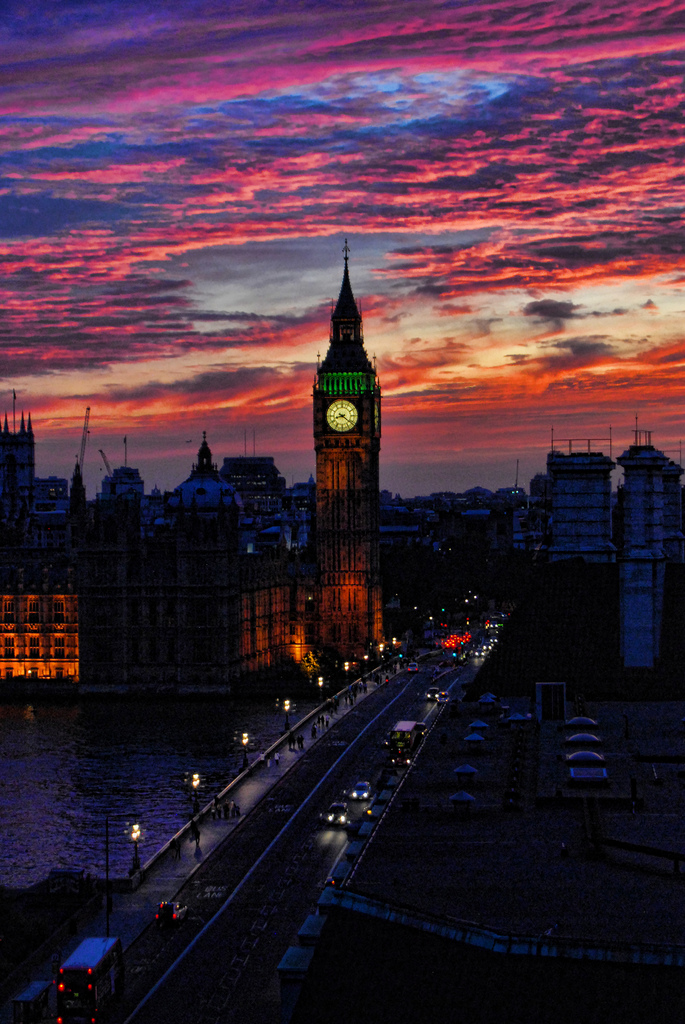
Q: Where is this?
A: This is at the city.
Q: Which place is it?
A: It is a city.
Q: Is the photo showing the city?
A: Yes, it is showing the city.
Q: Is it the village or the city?
A: It is the city.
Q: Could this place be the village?
A: No, it is the city.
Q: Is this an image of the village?
A: No, the picture is showing the city.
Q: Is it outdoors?
A: Yes, it is outdoors.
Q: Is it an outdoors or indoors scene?
A: It is outdoors.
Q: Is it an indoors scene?
A: No, it is outdoors.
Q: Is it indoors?
A: No, it is outdoors.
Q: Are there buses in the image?
A: Yes, there is a bus.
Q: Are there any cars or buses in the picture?
A: Yes, there is a bus.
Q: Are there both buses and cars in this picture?
A: Yes, there are both a bus and a car.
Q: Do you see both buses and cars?
A: Yes, there are both a bus and a car.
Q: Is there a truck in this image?
A: No, there are no trucks.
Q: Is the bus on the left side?
A: Yes, the bus is on the left of the image.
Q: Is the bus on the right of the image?
A: No, the bus is on the left of the image.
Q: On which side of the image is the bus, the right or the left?
A: The bus is on the left of the image.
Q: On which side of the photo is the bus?
A: The bus is on the left of the image.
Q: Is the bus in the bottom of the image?
A: Yes, the bus is in the bottom of the image.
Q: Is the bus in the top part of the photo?
A: No, the bus is in the bottom of the image.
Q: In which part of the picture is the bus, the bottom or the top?
A: The bus is in the bottom of the image.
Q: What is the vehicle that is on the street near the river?
A: The vehicle is a bus.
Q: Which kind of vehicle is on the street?
A: The vehicle is a bus.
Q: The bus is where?
A: The bus is on the street.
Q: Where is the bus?
A: The bus is on the street.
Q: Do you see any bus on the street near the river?
A: Yes, there is a bus on the street.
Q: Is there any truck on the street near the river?
A: No, there is a bus on the street.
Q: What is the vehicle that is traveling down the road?
A: The vehicle is a bus.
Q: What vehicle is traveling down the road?
A: The vehicle is a bus.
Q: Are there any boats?
A: No, there are no boats.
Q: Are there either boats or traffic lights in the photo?
A: No, there are no boats or traffic lights.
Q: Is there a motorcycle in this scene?
A: No, there are no motorcycles.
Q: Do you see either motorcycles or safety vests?
A: No, there are no motorcycles or safety vests.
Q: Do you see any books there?
A: No, there are no books.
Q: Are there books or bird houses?
A: No, there are no books or bird houses.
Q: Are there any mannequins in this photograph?
A: No, there are no mannequins.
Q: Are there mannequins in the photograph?
A: No, there are no mannequins.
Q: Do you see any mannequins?
A: No, there are no mannequins.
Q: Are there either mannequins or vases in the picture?
A: No, there are no mannequins or vases.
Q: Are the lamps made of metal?
A: Yes, the lamps are made of metal.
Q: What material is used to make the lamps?
A: The lamps are made of metal.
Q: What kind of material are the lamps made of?
A: The lamps are made of metal.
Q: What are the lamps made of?
A: The lamps are made of metal.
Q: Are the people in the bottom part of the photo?
A: Yes, the people are in the bottom of the image.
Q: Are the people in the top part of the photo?
A: No, the people are in the bottom of the image.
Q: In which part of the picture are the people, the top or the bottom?
A: The people are in the bottom of the image.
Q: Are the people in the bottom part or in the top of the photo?
A: The people are in the bottom of the image.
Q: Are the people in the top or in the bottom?
A: The people are in the bottom of the image.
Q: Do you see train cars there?
A: No, there are no train cars.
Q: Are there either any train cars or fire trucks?
A: No, there are no train cars or fire trucks.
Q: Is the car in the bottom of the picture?
A: Yes, the car is in the bottom of the image.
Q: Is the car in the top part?
A: No, the car is in the bottom of the image.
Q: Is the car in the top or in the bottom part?
A: The car is in the bottom of the image.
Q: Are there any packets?
A: No, there are no packets.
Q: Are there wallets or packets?
A: No, there are no packets or wallets.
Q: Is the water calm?
A: Yes, the water is calm.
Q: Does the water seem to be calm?
A: Yes, the water is calm.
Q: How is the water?
A: The water is calm.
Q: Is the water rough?
A: No, the water is calm.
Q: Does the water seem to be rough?
A: No, the water is calm.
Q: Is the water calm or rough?
A: The water is calm.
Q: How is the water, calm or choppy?
A: The water is calm.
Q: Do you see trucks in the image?
A: No, there are no trucks.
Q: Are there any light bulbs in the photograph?
A: No, there are no light bulbs.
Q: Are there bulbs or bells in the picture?
A: No, there are no bulbs or bells.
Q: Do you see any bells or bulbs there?
A: No, there are no bulbs or bells.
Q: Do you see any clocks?
A: Yes, there is a clock.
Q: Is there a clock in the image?
A: Yes, there is a clock.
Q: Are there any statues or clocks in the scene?
A: Yes, there is a clock.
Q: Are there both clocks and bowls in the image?
A: No, there is a clock but no bowls.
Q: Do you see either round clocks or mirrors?
A: Yes, there is a round clock.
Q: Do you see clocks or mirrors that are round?
A: Yes, the clock is round.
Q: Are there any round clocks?
A: Yes, there is a round clock.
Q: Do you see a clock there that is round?
A: Yes, there is a clock that is round.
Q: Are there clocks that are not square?
A: Yes, there is a round clock.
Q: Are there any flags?
A: No, there are no flags.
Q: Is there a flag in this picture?
A: No, there are no flags.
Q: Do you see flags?
A: No, there are no flags.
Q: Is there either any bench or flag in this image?
A: No, there are no flags or benches.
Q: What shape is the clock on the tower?
A: The clock is round.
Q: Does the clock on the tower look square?
A: No, the clock is round.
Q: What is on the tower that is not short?
A: The clock is on the tower.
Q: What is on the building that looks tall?
A: The clock is on the tower.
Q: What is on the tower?
A: The clock is on the tower.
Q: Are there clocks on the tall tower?
A: Yes, there is a clock on the tower.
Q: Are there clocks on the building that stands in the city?
A: Yes, there is a clock on the tower.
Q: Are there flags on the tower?
A: No, there is a clock on the tower.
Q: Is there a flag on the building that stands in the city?
A: No, there is a clock on the tower.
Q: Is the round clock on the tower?
A: Yes, the clock is on the tower.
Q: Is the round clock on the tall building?
A: Yes, the clock is on the tower.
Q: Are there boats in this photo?
A: No, there are no boats.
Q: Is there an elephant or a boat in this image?
A: No, there are no boats or elephants.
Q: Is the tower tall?
A: Yes, the tower is tall.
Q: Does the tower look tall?
A: Yes, the tower is tall.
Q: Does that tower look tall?
A: Yes, the tower is tall.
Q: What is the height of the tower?
A: The tower is tall.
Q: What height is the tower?
A: The tower is tall.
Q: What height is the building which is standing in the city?
A: The tower is tall.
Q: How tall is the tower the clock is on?
A: The tower is tall.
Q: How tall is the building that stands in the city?
A: The tower is tall.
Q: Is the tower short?
A: No, the tower is tall.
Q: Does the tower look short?
A: No, the tower is tall.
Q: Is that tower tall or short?
A: The tower is tall.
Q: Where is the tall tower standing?
A: The tower is standing in the city.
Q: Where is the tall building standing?
A: The tower is standing in the city.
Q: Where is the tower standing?
A: The tower is standing in the city.